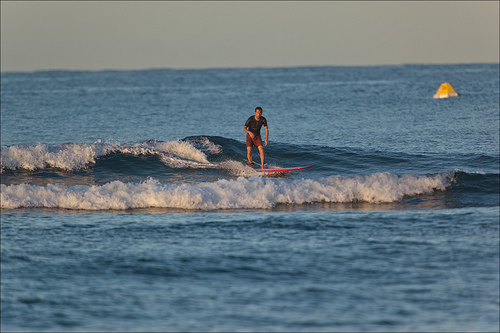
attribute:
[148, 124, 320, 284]
ocean — blue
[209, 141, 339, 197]
surfboard — red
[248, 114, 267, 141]
shirt — black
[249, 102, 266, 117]
hair — brown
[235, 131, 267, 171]
shorts — red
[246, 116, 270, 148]
shirt — black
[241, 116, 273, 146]
shirt — black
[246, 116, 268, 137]
shirt — black 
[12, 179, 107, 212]
ripples — small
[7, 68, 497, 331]
water — blue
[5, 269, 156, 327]
ripples — small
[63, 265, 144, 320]
ripples — small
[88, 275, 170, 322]
ripples — small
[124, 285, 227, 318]
ripples — small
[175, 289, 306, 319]
ripples — small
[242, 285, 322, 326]
ripples — small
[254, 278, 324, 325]
ripples — small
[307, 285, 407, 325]
ripples — small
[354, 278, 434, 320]
ripples — small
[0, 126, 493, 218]
wave — small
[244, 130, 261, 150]
trunks — red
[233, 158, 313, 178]
surfboard — red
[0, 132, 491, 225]
waves — crashing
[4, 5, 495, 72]
sky — gray, dusky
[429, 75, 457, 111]
buoy — floating, yellow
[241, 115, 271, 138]
top — dark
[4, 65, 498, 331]
ocean — deep blue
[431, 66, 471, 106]
buoy — yellow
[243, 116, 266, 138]
shirt — black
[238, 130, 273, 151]
shorts — red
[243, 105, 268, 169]
surfer — red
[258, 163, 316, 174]
surfboard — red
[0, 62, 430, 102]
horizon — empty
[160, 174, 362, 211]
reflection — slight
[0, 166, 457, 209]
wave — white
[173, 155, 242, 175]
wake — small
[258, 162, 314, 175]
surfboard — swimming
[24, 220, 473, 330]
water — blue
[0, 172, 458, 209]
water wave — white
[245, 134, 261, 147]
shorts — brown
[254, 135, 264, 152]
short — grey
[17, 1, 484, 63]
gray sky — cloudy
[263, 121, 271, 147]
arm — man's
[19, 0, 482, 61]
grey sky — clear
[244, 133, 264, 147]
trunks — red, swimming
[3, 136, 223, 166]
waves — white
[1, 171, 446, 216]
waves — white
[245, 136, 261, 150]
shorts — red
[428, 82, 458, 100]
buoy — yellow